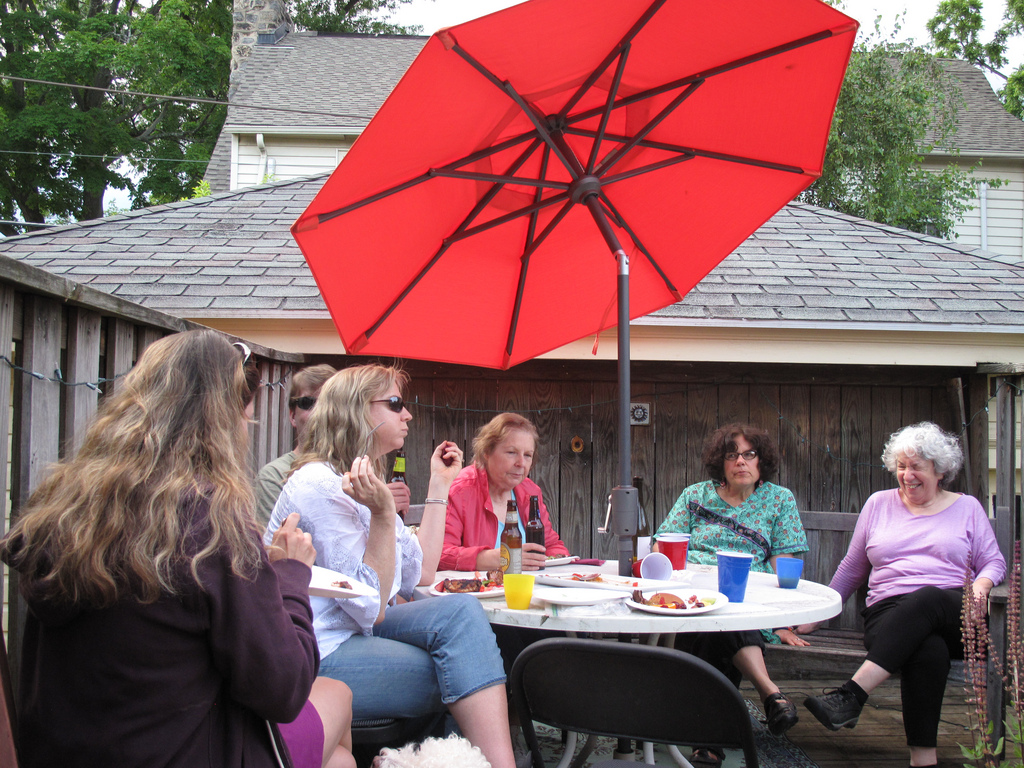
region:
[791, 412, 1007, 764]
The woman wearing black sneakers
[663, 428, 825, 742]
A brown curly haired woman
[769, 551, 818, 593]
The small plastic cup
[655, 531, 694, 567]
The red plastic cup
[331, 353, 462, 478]
the head of a woman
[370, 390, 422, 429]
the sunglasses of a woman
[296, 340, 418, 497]
the hair of a woman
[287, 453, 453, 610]
the hand of a woman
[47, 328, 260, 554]
the back of a woman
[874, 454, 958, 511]
the nose of a woman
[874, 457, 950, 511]
the eyes of a woman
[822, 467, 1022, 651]
a woman wearing a shirt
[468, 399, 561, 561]
woman sitting at the table with a bottle of beer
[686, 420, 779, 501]
glasses on the woman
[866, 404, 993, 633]
woman wearing a purple shirt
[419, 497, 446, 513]
bracelet on the wrist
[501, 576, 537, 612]
yellow cup on the table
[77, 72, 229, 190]
electrical wires above the building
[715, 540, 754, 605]
blue plastic cup on the table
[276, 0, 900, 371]
red umbrella over the women at the table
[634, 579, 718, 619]
plate of food on the table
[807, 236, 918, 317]
roof of the building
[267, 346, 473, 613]
women with sunglasses on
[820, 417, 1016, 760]
lady with black pants and purple shirt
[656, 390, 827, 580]
woman in blue shirt wearing glasses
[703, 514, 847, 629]
blue cups sitting on white table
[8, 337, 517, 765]
Ladies with their legs crossed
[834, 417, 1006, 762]
lady in black pants legs crossed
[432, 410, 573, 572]
woman red jacket holding bottle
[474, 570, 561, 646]
yellow cup sitting on white table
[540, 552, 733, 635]
white plates sitting on white table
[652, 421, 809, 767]
woman with brown curly hair sitting on a chair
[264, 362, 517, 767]
blonde woman wearing black sunglasses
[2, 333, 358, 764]
woman with long dark blonde hair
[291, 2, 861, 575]
a red umbrella on a gray pole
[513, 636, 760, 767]
a black folding chair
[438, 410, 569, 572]
blonde woman wearing a pink jacket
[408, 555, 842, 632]
a blue cup on a white round table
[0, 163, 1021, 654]
a wooden fence next to a small wooden house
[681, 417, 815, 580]
a perosn sitting down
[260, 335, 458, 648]
a perosn sitting down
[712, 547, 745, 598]
small blue disposable cup on table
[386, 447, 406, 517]
brown beer bottle with small yellow label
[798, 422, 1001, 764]
woman in purple top has white hair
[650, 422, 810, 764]
woman in green floral top wears black pants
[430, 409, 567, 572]
woman in red jacket holds brown beer bottle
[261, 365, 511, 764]
woman in black sunglasses wears denim capris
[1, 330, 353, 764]
woman with long hair wears purple jacket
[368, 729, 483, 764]
white fluffy dog sits near woman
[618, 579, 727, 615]
round white plate of food on table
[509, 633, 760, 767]
black metal chair pulled up to white table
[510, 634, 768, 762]
a black chair back